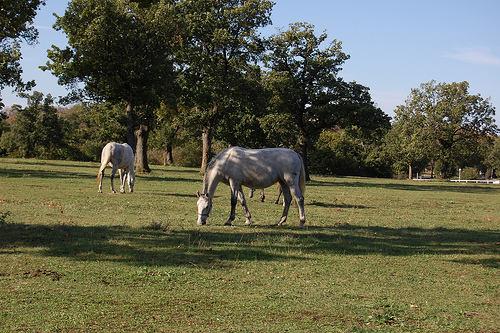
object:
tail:
[294, 154, 305, 197]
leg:
[227, 179, 239, 221]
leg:
[276, 180, 291, 219]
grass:
[0, 156, 499, 332]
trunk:
[130, 124, 154, 173]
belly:
[240, 173, 278, 188]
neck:
[199, 167, 219, 196]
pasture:
[0, 155, 499, 332]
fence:
[410, 178, 500, 183]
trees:
[36, 0, 278, 171]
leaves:
[28, 128, 36, 132]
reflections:
[230, 151, 268, 172]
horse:
[194, 146, 308, 225]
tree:
[366, 81, 499, 180]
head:
[194, 190, 213, 225]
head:
[126, 170, 137, 192]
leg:
[282, 174, 306, 218]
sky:
[1, 0, 500, 139]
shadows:
[0, 221, 500, 268]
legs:
[234, 185, 251, 218]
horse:
[98, 142, 137, 194]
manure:
[19, 267, 60, 279]